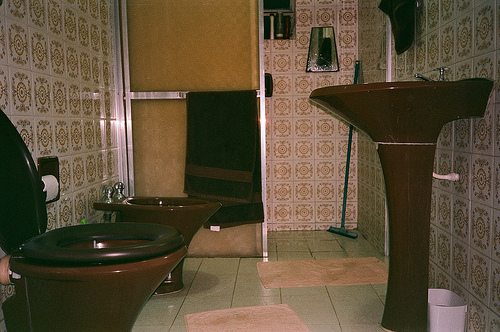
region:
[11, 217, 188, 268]
a black toilet seat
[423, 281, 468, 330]
a white trash can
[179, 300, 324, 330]
a pink bath mat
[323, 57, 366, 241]
a green broom in the corner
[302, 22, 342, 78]
a mirror on the wall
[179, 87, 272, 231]
a brown towel on the rack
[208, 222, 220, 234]
a white tag on the towel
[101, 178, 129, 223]
silver pipes behind the toilet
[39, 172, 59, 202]
a roll of toilet paper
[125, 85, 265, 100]
a metal towel rack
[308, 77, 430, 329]
Brown bathroom sink.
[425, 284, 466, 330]
Little white trash can under the sink.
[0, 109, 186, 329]
Brown toilet with the lid up.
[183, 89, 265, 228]
Brown and black towel hanging on the shower.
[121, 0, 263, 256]
Frosted glass shower door.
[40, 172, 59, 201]
A small roll of toilet paper.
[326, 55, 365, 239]
A green broom.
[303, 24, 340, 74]
A trapezoid shaped mirror on the wall.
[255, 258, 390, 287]
A peach colored towel on the floor.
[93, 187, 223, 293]
A brown bidet.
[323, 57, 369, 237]
A mop in the corner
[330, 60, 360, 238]
The mop is dirty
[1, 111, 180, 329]
A brown toilet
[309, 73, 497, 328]
A dirty brown sink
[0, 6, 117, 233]
The wall is tiled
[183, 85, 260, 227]
A brown bath towel is hanging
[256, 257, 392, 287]
A rug on the floor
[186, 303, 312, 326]
A rug on the floor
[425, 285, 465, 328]
A white plastic trash bucket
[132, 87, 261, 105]
A metal towel rack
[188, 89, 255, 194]
this is a towel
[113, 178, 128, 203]
this is a tap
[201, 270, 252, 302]
this is the floor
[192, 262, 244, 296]
the floor is made of tiles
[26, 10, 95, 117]
this is the wall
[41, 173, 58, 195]
this is a tissue paper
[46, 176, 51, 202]
the tissue paper is white in color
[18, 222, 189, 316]
this is a toilet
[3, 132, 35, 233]
this is the lid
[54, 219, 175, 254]
the toilet pit is uncovered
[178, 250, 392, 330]
Rugs on the floor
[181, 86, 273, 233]
Towel hanging on the bar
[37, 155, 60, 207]
Toilet paper holder on the wall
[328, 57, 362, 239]
Mop in the corner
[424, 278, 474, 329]
Garbage can under the sink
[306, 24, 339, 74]
Mirror on the wall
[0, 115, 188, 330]
Brown toilet with breen seat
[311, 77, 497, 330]
Brown sink attached to the wall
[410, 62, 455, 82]
Silver faucet over the sink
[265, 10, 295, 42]
Toiletries on the holder